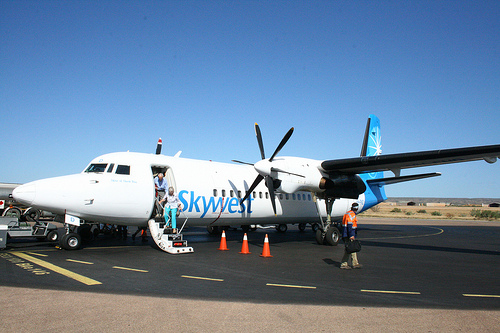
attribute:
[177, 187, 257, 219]
airline name — skywest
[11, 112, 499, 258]
airplane — idle, parked, private plane, small, painted white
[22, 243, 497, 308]
runway — black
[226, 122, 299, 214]
propeller — black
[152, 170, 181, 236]
passengers — unloading, leaving airplane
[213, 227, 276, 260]
cones — on grond, orange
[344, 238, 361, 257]
with bag — black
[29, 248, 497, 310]
stripes — yellow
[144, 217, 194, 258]
ladder — on airplane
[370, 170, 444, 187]
back wing — blue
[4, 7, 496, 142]
sky — blue, clear, cloudless, beautiful